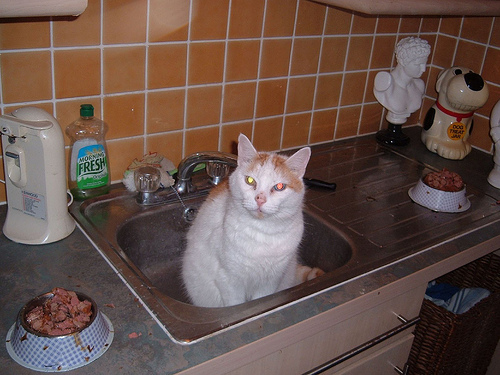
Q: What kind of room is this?
A: It is a kitchen.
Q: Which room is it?
A: It is a kitchen.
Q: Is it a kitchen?
A: Yes, it is a kitchen.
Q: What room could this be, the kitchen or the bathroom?
A: It is the kitchen.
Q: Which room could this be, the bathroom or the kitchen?
A: It is the kitchen.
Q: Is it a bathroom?
A: No, it is a kitchen.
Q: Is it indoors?
A: Yes, it is indoors.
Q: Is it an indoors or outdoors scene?
A: It is indoors.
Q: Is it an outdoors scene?
A: No, it is indoors.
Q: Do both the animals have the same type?
A: No, they are dogs and cats.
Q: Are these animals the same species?
A: No, they are dogs and cats.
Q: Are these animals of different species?
A: Yes, they are dogs and cats.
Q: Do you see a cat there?
A: Yes, there is a cat.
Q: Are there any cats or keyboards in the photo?
A: Yes, there is a cat.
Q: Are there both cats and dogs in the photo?
A: Yes, there are both a cat and a dog.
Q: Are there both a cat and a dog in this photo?
A: Yes, there are both a cat and a dog.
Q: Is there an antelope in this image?
A: No, there are no antelopes.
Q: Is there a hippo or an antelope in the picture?
A: No, there are no antelopes or hippos.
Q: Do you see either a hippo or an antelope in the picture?
A: No, there are no antelopes or hippos.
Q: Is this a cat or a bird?
A: This is a cat.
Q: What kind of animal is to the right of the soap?
A: The animal is a cat.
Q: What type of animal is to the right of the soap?
A: The animal is a cat.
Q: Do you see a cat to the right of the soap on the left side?
A: Yes, there is a cat to the right of the soap.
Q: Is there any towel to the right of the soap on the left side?
A: No, there is a cat to the right of the soap.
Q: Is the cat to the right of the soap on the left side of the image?
A: Yes, the cat is to the right of the soap.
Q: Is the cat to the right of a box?
A: No, the cat is to the right of the soap.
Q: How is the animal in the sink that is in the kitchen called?
A: The animal is a cat.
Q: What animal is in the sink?
A: The animal is a cat.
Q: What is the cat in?
A: The cat is in the sink.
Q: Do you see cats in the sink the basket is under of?
A: Yes, there is a cat in the sink.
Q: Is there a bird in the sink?
A: No, there is a cat in the sink.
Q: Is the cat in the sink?
A: Yes, the cat is in the sink.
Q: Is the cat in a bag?
A: No, the cat is in the sink.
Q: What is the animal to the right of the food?
A: The animal is a cat.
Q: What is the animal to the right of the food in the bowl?
A: The animal is a cat.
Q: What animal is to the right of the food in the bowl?
A: The animal is a cat.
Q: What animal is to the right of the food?
A: The animal is a cat.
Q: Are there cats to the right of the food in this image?
A: Yes, there is a cat to the right of the food.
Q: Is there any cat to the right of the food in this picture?
A: Yes, there is a cat to the right of the food.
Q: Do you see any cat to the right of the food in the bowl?
A: Yes, there is a cat to the right of the food.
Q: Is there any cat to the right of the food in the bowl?
A: Yes, there is a cat to the right of the food.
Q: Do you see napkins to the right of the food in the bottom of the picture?
A: No, there is a cat to the right of the food.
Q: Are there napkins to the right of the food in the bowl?
A: No, there is a cat to the right of the food.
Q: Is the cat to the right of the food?
A: Yes, the cat is to the right of the food.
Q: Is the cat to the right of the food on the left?
A: Yes, the cat is to the right of the food.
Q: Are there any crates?
A: No, there are no crates.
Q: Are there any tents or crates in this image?
A: No, there are no crates or tents.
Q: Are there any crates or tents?
A: No, there are no crates or tents.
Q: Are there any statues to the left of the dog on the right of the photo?
A: Yes, there is a statue to the left of the dog.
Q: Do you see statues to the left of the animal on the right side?
A: Yes, there is a statue to the left of the dog.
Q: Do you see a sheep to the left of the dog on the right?
A: No, there is a statue to the left of the dog.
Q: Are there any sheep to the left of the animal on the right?
A: No, there is a statue to the left of the dog.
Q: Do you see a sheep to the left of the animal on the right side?
A: No, there is a statue to the left of the dog.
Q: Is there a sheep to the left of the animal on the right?
A: No, there is a statue to the left of the dog.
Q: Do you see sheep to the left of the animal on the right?
A: No, there is a statue to the left of the dog.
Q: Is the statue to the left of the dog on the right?
A: Yes, the statue is to the left of the dog.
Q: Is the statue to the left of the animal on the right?
A: Yes, the statue is to the left of the dog.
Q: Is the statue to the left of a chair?
A: No, the statue is to the left of the dog.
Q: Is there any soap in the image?
A: Yes, there is a soap.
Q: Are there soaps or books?
A: Yes, there is a soap.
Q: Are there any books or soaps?
A: Yes, there is a soap.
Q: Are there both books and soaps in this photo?
A: No, there is a soap but no books.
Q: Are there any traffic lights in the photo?
A: No, there are no traffic lights.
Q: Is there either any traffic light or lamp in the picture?
A: No, there are no traffic lights or lamps.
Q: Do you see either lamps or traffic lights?
A: No, there are no traffic lights or lamps.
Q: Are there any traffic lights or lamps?
A: No, there are no traffic lights or lamps.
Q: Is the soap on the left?
A: Yes, the soap is on the left of the image.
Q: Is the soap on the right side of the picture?
A: No, the soap is on the left of the image.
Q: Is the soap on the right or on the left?
A: The soap is on the left of the image.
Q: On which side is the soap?
A: The soap is on the left of the image.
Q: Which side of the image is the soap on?
A: The soap is on the left of the image.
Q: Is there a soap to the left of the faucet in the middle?
A: Yes, there is a soap to the left of the faucet.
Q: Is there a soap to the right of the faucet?
A: No, the soap is to the left of the faucet.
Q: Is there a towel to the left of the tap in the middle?
A: No, there is a soap to the left of the tap.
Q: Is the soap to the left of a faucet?
A: Yes, the soap is to the left of a faucet.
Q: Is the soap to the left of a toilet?
A: No, the soap is to the left of a faucet.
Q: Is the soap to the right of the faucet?
A: No, the soap is to the left of the faucet.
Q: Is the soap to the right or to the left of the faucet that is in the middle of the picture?
A: The soap is to the left of the tap.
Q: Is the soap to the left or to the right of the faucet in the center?
A: The soap is to the left of the tap.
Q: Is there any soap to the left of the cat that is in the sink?
A: Yes, there is a soap to the left of the cat.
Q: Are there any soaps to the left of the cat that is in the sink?
A: Yes, there is a soap to the left of the cat.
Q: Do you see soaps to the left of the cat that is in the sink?
A: Yes, there is a soap to the left of the cat.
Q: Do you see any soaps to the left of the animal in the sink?
A: Yes, there is a soap to the left of the cat.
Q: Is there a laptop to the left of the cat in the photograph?
A: No, there is a soap to the left of the cat.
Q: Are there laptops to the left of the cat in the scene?
A: No, there is a soap to the left of the cat.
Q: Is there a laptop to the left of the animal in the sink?
A: No, there is a soap to the left of the cat.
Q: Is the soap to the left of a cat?
A: Yes, the soap is to the left of a cat.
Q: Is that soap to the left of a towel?
A: No, the soap is to the left of a cat.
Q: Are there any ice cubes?
A: No, there are no ice cubes.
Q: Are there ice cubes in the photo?
A: No, there are no ice cubes.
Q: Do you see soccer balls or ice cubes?
A: No, there are no ice cubes or soccer balls.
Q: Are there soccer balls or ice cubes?
A: No, there are no ice cubes or soccer balls.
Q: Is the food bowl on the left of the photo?
A: Yes, the bowl is on the left of the image.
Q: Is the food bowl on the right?
A: No, the bowl is on the left of the image.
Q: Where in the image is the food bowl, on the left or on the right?
A: The bowl is on the left of the image.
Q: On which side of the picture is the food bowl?
A: The bowl is on the left of the image.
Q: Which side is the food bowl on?
A: The bowl is on the left of the image.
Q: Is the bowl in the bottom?
A: Yes, the bowl is in the bottom of the image.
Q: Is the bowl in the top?
A: No, the bowl is in the bottom of the image.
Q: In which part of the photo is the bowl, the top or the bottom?
A: The bowl is in the bottom of the image.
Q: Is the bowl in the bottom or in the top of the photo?
A: The bowl is in the bottom of the image.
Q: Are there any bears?
A: No, there are no bears.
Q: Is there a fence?
A: No, there are no fences.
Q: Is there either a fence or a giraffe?
A: No, there are no fences or giraffes.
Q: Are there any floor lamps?
A: No, there are no floor lamps.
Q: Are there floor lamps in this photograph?
A: No, there are no floor lamps.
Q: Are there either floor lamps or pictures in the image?
A: No, there are no floor lamps or pictures.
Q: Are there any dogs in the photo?
A: Yes, there is a dog.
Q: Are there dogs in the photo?
A: Yes, there is a dog.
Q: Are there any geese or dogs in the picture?
A: Yes, there is a dog.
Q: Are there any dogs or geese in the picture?
A: Yes, there is a dog.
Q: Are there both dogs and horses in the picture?
A: No, there is a dog but no horses.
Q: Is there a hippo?
A: No, there are no hippos.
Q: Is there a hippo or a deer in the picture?
A: No, there are no hippos or deer.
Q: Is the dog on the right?
A: Yes, the dog is on the right of the image.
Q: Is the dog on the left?
A: No, the dog is on the right of the image.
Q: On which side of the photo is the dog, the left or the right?
A: The dog is on the right of the image.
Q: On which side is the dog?
A: The dog is on the right of the image.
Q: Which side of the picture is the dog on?
A: The dog is on the right of the image.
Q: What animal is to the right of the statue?
A: The animal is a dog.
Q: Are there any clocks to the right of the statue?
A: No, there is a dog to the right of the statue.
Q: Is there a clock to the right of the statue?
A: No, there is a dog to the right of the statue.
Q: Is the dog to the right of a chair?
A: No, the dog is to the right of the statue.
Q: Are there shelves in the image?
A: No, there are no shelves.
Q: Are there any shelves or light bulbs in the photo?
A: No, there are no shelves or light bulbs.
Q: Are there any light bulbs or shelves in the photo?
A: No, there are no shelves or light bulbs.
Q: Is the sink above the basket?
A: Yes, the sink is above the basket.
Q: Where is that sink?
A: The sink is in the kitchen.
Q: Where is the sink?
A: The sink is in the kitchen.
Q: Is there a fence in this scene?
A: No, there are no fences.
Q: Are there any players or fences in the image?
A: No, there are no fences or players.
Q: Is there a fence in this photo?
A: No, there are no fences.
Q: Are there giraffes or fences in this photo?
A: No, there are no fences or giraffes.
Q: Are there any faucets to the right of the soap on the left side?
A: Yes, there is a faucet to the right of the soap.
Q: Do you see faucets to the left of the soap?
A: No, the faucet is to the right of the soap.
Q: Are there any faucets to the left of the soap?
A: No, the faucet is to the right of the soap.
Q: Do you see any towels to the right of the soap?
A: No, there is a faucet to the right of the soap.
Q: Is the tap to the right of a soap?
A: Yes, the tap is to the right of a soap.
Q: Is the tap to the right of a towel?
A: No, the tap is to the right of a soap.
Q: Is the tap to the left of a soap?
A: No, the tap is to the right of a soap.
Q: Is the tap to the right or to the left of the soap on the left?
A: The tap is to the right of the soap.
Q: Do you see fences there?
A: No, there are no fences.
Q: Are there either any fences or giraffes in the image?
A: No, there are no fences or giraffes.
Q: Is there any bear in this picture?
A: No, there are no bears.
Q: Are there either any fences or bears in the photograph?
A: No, there are no bears or fences.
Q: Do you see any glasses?
A: No, there are no glasses.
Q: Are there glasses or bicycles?
A: No, there are no glasses or bicycles.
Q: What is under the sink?
A: The basket is under the sink.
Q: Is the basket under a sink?
A: Yes, the basket is under a sink.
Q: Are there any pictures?
A: No, there are no pictures.